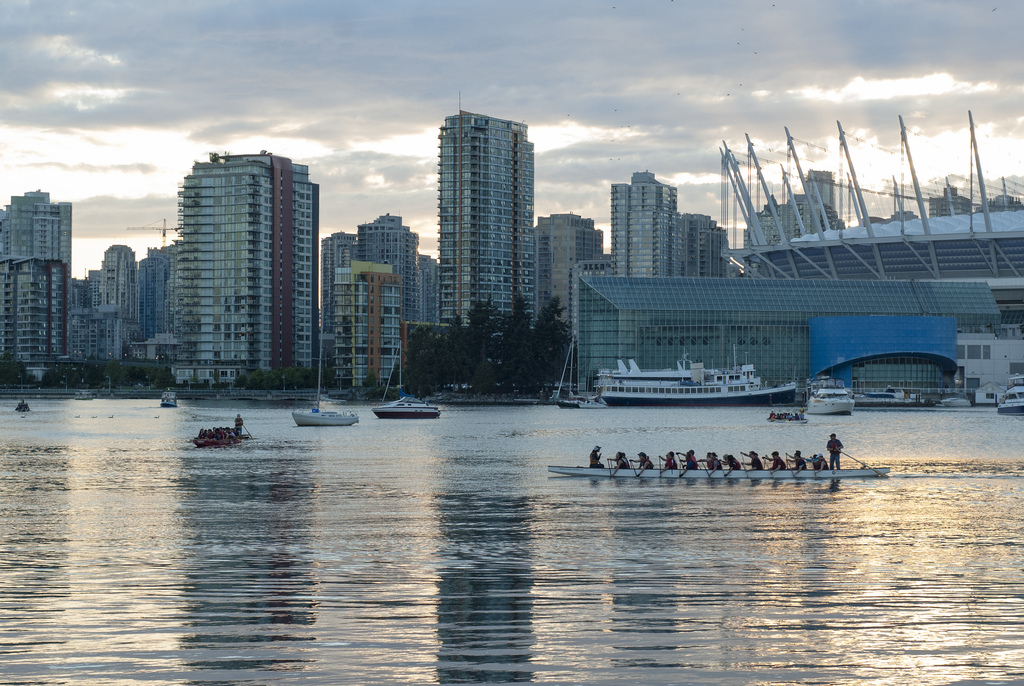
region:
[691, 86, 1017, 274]
the stadium looking building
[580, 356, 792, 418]
The big cruise ship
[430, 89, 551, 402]
the tallest building on the skyline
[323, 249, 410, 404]
The shortest tower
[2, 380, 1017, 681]
The ater in the barbor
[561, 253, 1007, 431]
the short glass building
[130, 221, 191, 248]
the crane off in the distance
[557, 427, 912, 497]
crew rowing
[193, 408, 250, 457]
red boat in water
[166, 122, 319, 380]
large building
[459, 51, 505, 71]
white clouds in blue sky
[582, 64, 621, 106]
white clouds in blue sky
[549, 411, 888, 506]
Long white canoe full of people.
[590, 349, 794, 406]
Large white boat.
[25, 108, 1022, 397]
Tall buildings with lots of window's.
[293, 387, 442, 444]
Two small boats on water.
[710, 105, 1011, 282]
Sport's stadium with metal poles.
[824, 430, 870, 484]
Person standing in canoe with a paddle.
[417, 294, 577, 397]
Small group of trees by buildings.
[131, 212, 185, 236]
A crane arm in the distance.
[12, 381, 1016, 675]
Body of water with boats and canoes.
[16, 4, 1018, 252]
Dark clouds in the sky.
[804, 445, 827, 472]
person on the boat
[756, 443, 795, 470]
person on the boat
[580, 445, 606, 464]
person on the boat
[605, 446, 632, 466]
person on the boat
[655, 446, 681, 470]
person on the boat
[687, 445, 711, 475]
person on the boat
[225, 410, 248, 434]
person on the boat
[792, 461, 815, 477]
person on the boat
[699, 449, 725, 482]
person on the boat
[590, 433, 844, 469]
people sitting on canoe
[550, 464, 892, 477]
large white canoe on lake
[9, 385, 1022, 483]
boats in lake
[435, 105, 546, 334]
tall building in the middle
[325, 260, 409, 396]
bricked building with white windows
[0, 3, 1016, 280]
gray cloudy sky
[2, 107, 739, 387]
buildings in the background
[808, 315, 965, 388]
blue wall behind boats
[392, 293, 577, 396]
big trees with green leaves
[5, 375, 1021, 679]
clear open water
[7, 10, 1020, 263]
cloudy morning sky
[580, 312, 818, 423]
large long white and blue boat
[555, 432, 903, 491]
long thin white racing boat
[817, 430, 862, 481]
man standing in racing boat